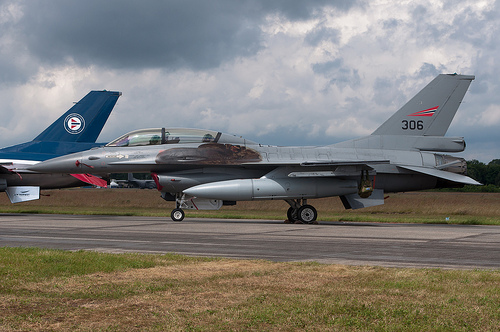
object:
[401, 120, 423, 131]
number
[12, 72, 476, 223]
plane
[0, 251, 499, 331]
grass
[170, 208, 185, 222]
wheel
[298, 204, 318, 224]
wheel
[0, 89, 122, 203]
plane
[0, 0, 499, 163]
sky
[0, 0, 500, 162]
cloud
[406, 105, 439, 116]
design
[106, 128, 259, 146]
cockpit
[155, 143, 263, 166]
rust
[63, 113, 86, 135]
circle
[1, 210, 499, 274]
runway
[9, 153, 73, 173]
nose